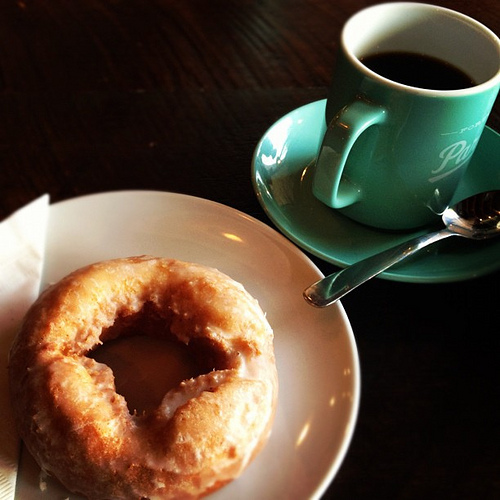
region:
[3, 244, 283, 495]
donut on plate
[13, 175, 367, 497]
white round plate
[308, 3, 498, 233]
green coffe cup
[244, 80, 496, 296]
small green plate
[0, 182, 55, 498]
paper napkin on side of plate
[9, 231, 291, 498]
brown donut with a sweet glaze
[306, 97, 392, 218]
handle of a green coffee cup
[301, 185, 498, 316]
spoon made of silver metal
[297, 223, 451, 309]
handle of a silver metal spoon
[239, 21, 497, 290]
green coffee cup on a green plate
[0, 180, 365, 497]
white plate with a donut on top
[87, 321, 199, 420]
hole of a brown donut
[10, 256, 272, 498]
Donut sitting on a plate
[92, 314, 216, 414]
Hole in the center of a donut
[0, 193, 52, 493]
White napkin on a plate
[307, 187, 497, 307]
A silver spoon on a green plate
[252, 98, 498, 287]
Green plate underneath a cup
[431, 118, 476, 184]
Writing on a green cup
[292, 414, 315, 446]
Reflection on a white plate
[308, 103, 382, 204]
A handle on a green cup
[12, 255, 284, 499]
Donut with a sugar glaze.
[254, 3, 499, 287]
Mug of coffee and a saucer.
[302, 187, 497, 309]
Silver tea spoon.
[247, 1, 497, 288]
Green coffee mug and matching saucer.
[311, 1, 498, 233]
Mug of coffee.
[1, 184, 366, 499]
Donut on a white plate.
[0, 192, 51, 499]
White paper napkin.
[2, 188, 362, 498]
Small plate with a donut and napkin on it.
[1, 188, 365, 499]
White plate.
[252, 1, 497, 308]
Mug and spoon on a saucer.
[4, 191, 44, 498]
A white napkin on a plate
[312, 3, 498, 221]
A green cup filled with coffee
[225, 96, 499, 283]
A small green plate with a cup on it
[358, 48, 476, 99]
Black coffee in a cup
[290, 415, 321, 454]
Light reflected on a plate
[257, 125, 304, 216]
A reflection on a plate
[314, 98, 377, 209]
A handle on a coffee cup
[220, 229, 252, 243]
Reflected light on a white plate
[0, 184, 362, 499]
Small white plate with a donut on it.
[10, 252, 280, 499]
Donut with a sugar glaze.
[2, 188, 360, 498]
White plate holding a napkin and donut.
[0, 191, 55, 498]
White paper napkin.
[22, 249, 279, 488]
the doughnut is brown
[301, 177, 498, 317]
silver spoon resting on green plate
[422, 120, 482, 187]
white writing on green coffee cup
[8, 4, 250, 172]
brown wooden breakfast table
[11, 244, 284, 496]
glazed cake donut on plate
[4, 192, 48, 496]
white paper napkin on plate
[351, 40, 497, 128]
black coffee in coffee cup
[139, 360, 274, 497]
crispy glazed bubble on donut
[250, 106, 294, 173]
reflection in light on saucer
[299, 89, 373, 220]
handle of green coffee cup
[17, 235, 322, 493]
a doughnut in the background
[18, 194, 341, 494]
a doughnut on a plate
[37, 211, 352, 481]
a brown doughnut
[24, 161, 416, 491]
a plate on the table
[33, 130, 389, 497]
a white plate on the table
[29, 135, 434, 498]
a shiny reflective plate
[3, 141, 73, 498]
a napkin on the plate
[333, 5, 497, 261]
a green cup